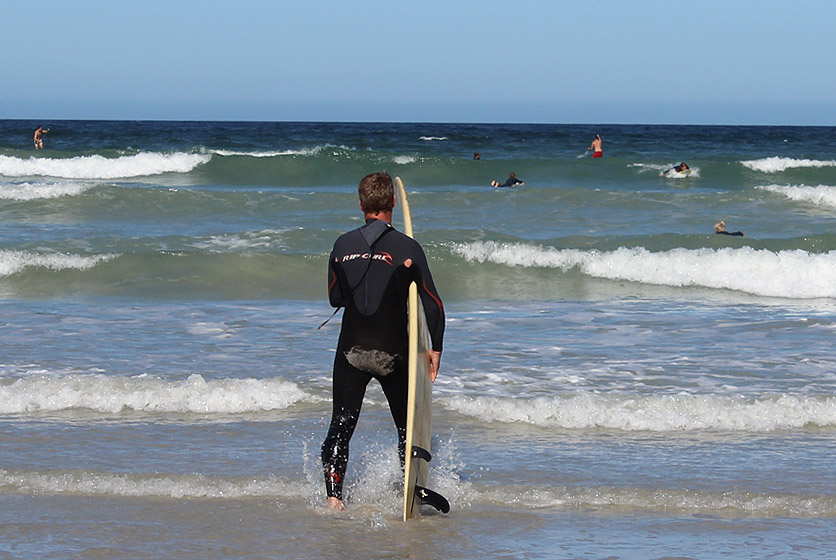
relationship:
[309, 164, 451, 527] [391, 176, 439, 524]
man holding surfboard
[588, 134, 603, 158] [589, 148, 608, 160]
man with shorts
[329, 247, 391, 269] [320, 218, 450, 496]
letters on wet suit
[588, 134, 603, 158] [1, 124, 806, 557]
man swimming in water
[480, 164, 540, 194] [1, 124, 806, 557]
person swimming in water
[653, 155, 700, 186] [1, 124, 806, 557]
person swimming in water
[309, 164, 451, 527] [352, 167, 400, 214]
man has hair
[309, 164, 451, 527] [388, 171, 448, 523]
man holding surfboard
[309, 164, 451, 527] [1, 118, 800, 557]
man walking into ocean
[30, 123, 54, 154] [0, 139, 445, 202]
surfer riding wave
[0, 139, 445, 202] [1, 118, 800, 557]
wave in ocean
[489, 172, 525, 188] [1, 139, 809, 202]
person paddling into wave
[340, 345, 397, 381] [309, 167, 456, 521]
sand stuck to surfboarder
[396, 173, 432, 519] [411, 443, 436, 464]
surfboard has fin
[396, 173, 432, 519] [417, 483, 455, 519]
surfboard has fin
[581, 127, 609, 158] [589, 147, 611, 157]
man in shorts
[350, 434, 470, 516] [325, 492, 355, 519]
water splashing on feet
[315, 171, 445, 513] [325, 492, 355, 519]
man has feet